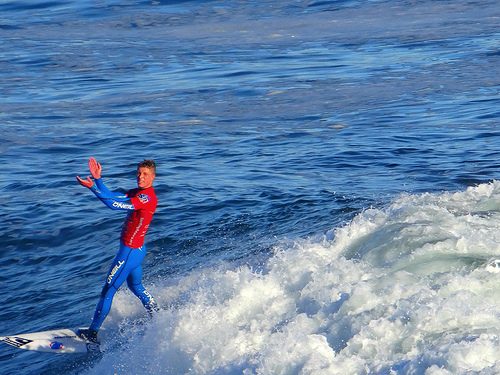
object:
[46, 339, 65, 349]
sticker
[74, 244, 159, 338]
pants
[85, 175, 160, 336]
wetsuit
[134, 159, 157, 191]
hair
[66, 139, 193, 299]
man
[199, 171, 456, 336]
waves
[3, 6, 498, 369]
water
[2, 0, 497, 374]
sea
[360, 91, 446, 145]
waves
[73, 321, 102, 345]
shoe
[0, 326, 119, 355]
surfboard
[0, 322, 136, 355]
white surfboard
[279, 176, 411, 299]
white water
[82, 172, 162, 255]
shirt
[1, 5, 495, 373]
ocean